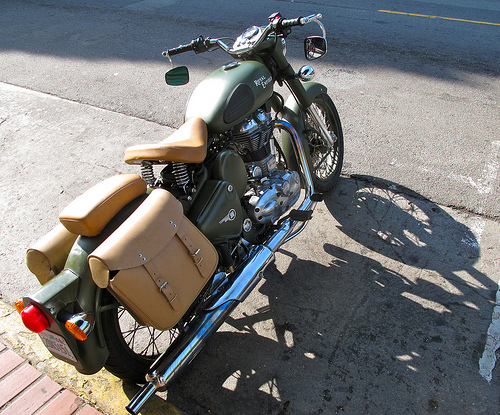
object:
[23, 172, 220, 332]
saddle backs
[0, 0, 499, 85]
shadow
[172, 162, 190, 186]
springs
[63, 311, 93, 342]
light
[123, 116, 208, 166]
motorbike seat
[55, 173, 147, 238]
seat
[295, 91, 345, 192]
round tire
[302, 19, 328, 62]
mirror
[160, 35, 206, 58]
handlebar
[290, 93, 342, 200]
tire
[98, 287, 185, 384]
tire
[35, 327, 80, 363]
plate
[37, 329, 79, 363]
license plate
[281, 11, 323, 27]
handlebars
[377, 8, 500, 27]
line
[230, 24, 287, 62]
light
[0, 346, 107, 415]
brick pathway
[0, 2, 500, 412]
road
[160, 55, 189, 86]
mirror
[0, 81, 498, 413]
parking spot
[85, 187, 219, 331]
bag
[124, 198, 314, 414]
exhaust pipe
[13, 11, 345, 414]
motorbike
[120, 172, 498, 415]
shadow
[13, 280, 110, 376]
back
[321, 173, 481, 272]
reflection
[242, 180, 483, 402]
sidewalk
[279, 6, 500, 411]
ground